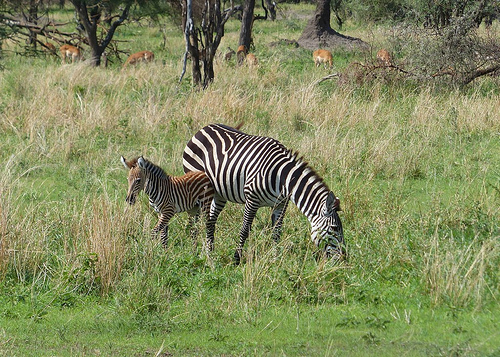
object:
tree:
[67, 0, 132, 64]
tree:
[237, 0, 255, 60]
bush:
[330, 0, 393, 24]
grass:
[0, 0, 500, 357]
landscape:
[0, 0, 500, 357]